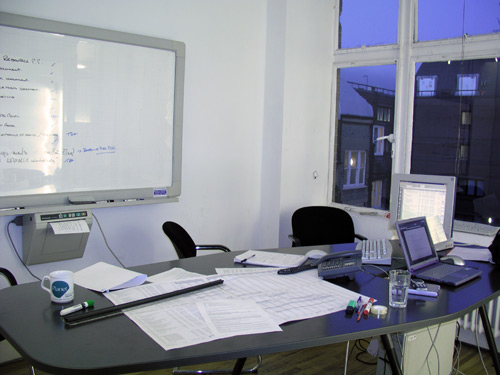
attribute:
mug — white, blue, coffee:
[40, 270, 73, 301]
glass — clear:
[387, 268, 409, 305]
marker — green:
[60, 300, 95, 315]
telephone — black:
[320, 250, 360, 278]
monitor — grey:
[387, 172, 454, 242]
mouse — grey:
[304, 247, 323, 256]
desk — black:
[6, 237, 498, 366]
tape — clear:
[369, 304, 389, 316]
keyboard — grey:
[360, 237, 390, 264]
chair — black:
[287, 203, 367, 243]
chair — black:
[161, 216, 230, 259]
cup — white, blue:
[39, 268, 76, 303]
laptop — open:
[393, 214, 481, 283]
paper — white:
[195, 295, 284, 330]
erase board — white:
[1, 14, 183, 202]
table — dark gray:
[1, 240, 498, 371]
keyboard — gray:
[355, 235, 390, 263]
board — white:
[0, 8, 187, 210]